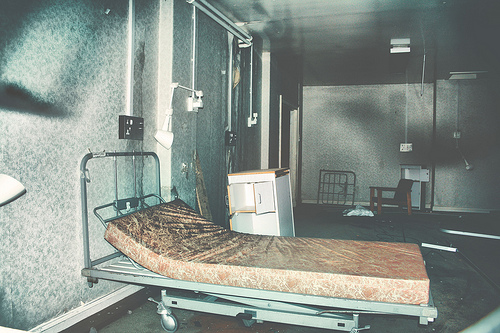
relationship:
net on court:
[334, 130, 364, 140] [385, 118, 479, 152]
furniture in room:
[280, 159, 427, 226] [64, 16, 455, 282]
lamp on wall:
[430, 118, 458, 184] [318, 93, 356, 121]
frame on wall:
[67, 138, 150, 190] [318, 93, 356, 121]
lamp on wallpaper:
[430, 118, 458, 184] [37, 37, 101, 82]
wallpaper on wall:
[37, 37, 101, 82] [318, 93, 356, 121]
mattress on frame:
[49, 177, 370, 289] [67, 138, 150, 190]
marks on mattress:
[150, 223, 195, 253] [49, 177, 370, 289]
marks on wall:
[150, 223, 195, 253] [318, 93, 356, 121]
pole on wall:
[415, 60, 430, 75] [318, 93, 356, 121]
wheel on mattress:
[156, 311, 178, 331] [49, 177, 370, 289]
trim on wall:
[148, 21, 182, 60] [318, 93, 356, 121]